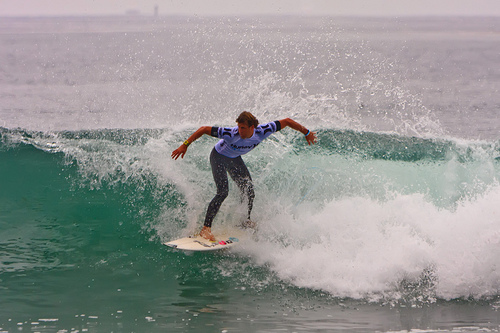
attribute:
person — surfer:
[172, 114, 317, 240]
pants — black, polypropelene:
[204, 148, 254, 225]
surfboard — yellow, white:
[162, 227, 259, 251]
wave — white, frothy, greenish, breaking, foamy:
[14, 126, 495, 286]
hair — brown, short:
[235, 111, 263, 129]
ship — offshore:
[126, 8, 144, 15]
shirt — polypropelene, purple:
[208, 124, 283, 157]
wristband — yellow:
[181, 138, 191, 148]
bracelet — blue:
[304, 129, 311, 137]